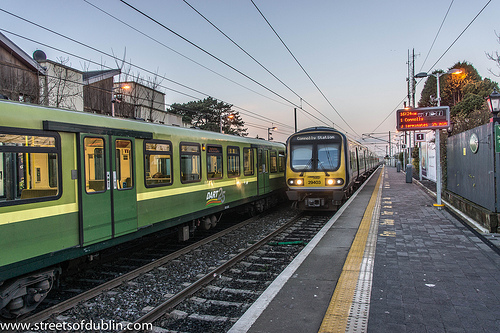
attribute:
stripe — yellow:
[7, 164, 277, 229]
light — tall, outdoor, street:
[393, 66, 471, 208]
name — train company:
[200, 184, 225, 211]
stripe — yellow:
[315, 170, 385, 331]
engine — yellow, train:
[277, 124, 353, 212]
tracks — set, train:
[130, 210, 305, 329]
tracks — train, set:
[75, 210, 301, 308]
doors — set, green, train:
[74, 129, 140, 248]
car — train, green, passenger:
[8, 92, 283, 310]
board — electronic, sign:
[392, 101, 452, 134]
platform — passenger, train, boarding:
[284, 160, 439, 328]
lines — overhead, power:
[9, 11, 449, 142]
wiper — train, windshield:
[312, 157, 331, 180]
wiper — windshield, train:
[299, 157, 312, 178]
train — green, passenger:
[8, 95, 282, 314]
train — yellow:
[273, 19, 484, 326]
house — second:
[35, 49, 92, 112]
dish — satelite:
[33, 44, 47, 62]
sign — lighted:
[391, 101, 459, 141]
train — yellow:
[283, 120, 379, 199]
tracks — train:
[141, 215, 319, 323]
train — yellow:
[280, 126, 353, 205]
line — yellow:
[131, 175, 260, 204]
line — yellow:
[314, 161, 390, 329]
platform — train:
[217, 159, 496, 329]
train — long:
[280, 123, 380, 214]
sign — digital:
[392, 104, 452, 134]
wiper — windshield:
[317, 160, 329, 179]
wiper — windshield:
[295, 157, 312, 177]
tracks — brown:
[149, 194, 332, 324]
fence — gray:
[442, 116, 499, 237]